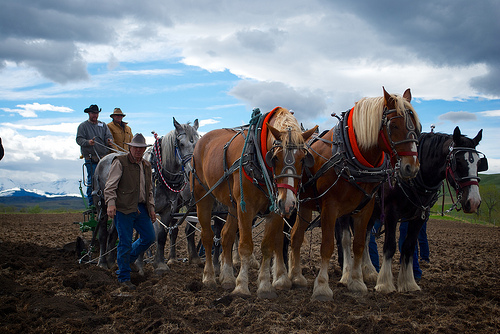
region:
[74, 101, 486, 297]
men behind plow horses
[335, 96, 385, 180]
blonde mane on neck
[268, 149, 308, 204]
bridle on horse face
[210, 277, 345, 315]
horse hooves in dirt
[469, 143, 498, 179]
blinder over horses eye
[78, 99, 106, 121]
cowboy hat on man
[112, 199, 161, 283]
jeans on walking man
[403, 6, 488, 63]
gray cloud in daytime sky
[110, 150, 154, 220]
brown vest on man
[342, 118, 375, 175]
red ring on horse neck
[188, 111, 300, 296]
a brown and white horse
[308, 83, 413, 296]
a brown and white horse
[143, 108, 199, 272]
a grey horse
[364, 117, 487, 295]
a black and white horse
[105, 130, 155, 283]
man dressed as a cowboy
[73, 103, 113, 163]
man dressed as a cowboy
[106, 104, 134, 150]
man dressed as a cowboy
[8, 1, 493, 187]
a cloudy blue sky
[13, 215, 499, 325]
a plowed dirt field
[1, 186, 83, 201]
snow capped mountains in distance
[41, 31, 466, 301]
plenty horses on field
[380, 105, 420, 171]
bridle on horse's head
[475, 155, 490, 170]
blinder on horse's eye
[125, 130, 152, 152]
hat on cowboy's head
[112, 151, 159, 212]
vest on cowboy's body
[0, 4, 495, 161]
clouds in the sky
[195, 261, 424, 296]
hooves of horses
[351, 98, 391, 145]
mane on horse's neck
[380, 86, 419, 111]
ears on horse's head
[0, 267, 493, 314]
dirt on ground under horses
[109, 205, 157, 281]
cowboy's legs walking forward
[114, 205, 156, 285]
dark blue denim jeans